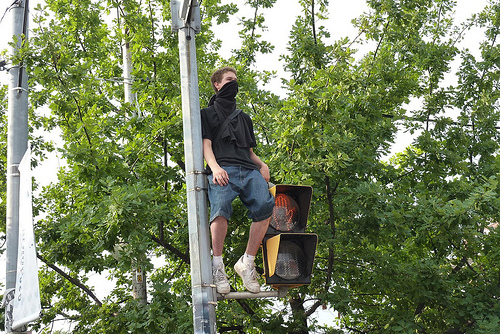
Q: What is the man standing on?
A: The pole.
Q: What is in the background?
A: Green trees.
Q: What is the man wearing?
A: A black shirt.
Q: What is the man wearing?
A: Blue shorts.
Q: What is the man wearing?
A: White shoes.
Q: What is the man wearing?
A: White sox.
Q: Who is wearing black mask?
A: A man.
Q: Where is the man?
A: Standing on light pole.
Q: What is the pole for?
A: Traffic lights.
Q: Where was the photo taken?
A: Outdoors somewhere.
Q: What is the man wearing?
A: Shorts.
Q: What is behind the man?
A: Trees.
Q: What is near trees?
A: The poles.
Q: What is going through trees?
A: Wires.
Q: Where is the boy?
A: On arm that holds light.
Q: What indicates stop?
A: The red light.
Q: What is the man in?
A: A black shirt.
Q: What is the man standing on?
A: The light.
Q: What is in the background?
A: Trees.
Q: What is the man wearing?
A: Jean shorts.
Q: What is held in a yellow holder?
A: Two lights.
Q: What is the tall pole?
A: Traffic pole.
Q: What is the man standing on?
A: A traffic pole.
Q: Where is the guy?
A: On the pole.